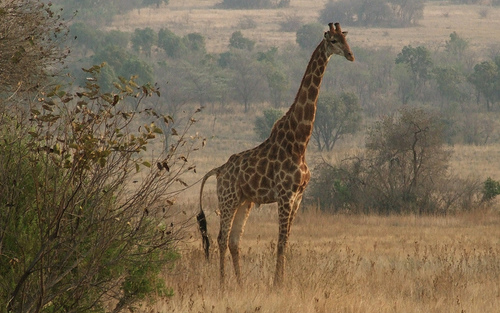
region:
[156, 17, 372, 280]
Giraffe standing in a field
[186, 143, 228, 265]
Tail of a giraffe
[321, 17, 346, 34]
Horns on a giraffe's head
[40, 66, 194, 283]
Bush in a field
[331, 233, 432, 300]
Brown grass in a field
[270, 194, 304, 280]
Front legs of a giraffe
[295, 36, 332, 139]
Long neck of a giraffe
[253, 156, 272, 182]
Brown spot on the side of a giraffe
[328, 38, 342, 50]
Black eye of a giraffe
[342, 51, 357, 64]
Mouth of a giraffe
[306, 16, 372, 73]
head of the giraffe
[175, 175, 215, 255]
tail of the giraffe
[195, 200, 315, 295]
legs of the giraffe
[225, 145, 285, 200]
brown spots on the giraffe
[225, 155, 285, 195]
white lines on giraffe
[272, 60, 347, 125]
neck of the giraffe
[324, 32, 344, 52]
eye of the giraffe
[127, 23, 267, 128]
trees in the distance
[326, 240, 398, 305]
grass next to giraffe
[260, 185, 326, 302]
front legs of the giraffe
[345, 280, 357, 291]
tip of a grass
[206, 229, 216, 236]
part of a tail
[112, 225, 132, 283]
part of a twig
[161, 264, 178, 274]
part of a bush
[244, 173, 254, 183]
part of a giraffe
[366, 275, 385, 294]
part of a grass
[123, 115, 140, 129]
edge of a leaf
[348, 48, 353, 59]
mouth of a giraffe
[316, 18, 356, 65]
head of a content looking giraffe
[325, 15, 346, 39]
a giraffe's ossicones on top of head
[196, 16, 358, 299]
a giraffe in natural wild habitat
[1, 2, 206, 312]
green and brown bushes in natural surroundings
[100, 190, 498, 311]
grazing field in a natural habitat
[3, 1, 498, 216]
grove of trees in a natural setting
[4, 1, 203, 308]
brown leaves on a field bush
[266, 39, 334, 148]
tall slender neck of a giraffe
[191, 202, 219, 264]
long tuft of hair on tail of a giraffe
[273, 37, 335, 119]
short stiff mane on giraffe's neck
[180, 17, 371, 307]
Giraffe standing in a field.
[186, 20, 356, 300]
The giraffe is brown and tan.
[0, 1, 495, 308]
Dry, dead landscape.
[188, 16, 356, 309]
Giraffe is standing in the dry foliage.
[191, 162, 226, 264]
Tail is pointed down.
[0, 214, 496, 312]
The plains are dry.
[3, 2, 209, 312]
The bush is leaning.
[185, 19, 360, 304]
The Giraffe is standing still.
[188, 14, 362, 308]
Giraffe standing outside.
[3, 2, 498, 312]
A lot of foliage in the area.